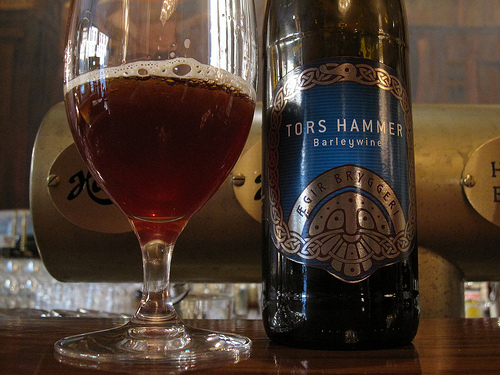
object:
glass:
[52, 0, 258, 374]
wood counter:
[0, 315, 499, 373]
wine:
[61, 74, 258, 250]